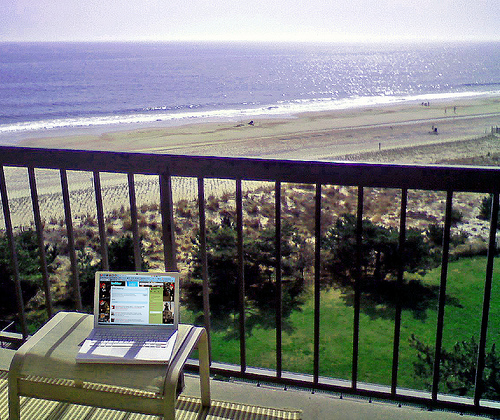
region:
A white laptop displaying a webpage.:
[87, 269, 185, 367]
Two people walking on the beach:
[437, 101, 462, 118]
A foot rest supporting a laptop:
[6, 269, 222, 418]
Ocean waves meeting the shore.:
[3, 106, 217, 132]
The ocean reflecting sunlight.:
[292, 41, 417, 86]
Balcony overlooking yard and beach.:
[2, 144, 487, 386]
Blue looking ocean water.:
[36, 54, 181, 90]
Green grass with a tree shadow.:
[317, 289, 442, 377]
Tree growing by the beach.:
[325, 85, 436, 310]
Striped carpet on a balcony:
[2, 315, 242, 418]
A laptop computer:
[65, 262, 197, 379]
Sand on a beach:
[228, 112, 468, 152]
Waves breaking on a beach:
[34, 100, 156, 137]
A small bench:
[4, 352, 196, 418]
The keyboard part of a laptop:
[91, 328, 177, 358]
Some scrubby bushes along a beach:
[192, 208, 434, 328]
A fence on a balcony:
[245, 155, 497, 388]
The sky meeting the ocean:
[26, 0, 234, 70]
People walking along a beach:
[410, 87, 468, 117]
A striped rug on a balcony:
[216, 393, 262, 418]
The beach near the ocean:
[187, 121, 440, 156]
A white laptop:
[70, 261, 182, 368]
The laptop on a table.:
[15, 265, 240, 415]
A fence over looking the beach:
[200, 155, 485, 415]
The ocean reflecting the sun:
[75, 50, 310, 102]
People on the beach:
[415, 97, 462, 113]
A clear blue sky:
[20, 0, 200, 30]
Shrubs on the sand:
[177, 195, 189, 245]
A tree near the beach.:
[210, 231, 235, 346]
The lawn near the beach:
[410, 297, 431, 337]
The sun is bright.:
[8, 5, 495, 127]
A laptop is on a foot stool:
[68, 245, 220, 400]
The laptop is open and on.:
[77, 251, 204, 394]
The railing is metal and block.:
[14, 149, 497, 416]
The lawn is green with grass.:
[303, 262, 498, 338]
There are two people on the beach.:
[433, 84, 481, 144]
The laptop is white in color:
[62, 264, 243, 374]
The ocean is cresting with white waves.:
[8, 93, 460, 120]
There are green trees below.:
[189, 229, 498, 399]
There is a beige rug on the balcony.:
[4, 358, 299, 418]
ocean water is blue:
[1, 37, 498, 117]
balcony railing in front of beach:
[0, 0, 495, 411]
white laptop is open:
[75, 265, 180, 365]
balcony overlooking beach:
[0, 0, 495, 410]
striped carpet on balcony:
[0, 361, 302, 416]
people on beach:
[246, 93, 496, 154]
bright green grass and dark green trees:
[2, 226, 495, 404]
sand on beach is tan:
[0, 101, 499, 236]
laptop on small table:
[7, 268, 214, 418]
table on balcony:
[9, 309, 211, 419]